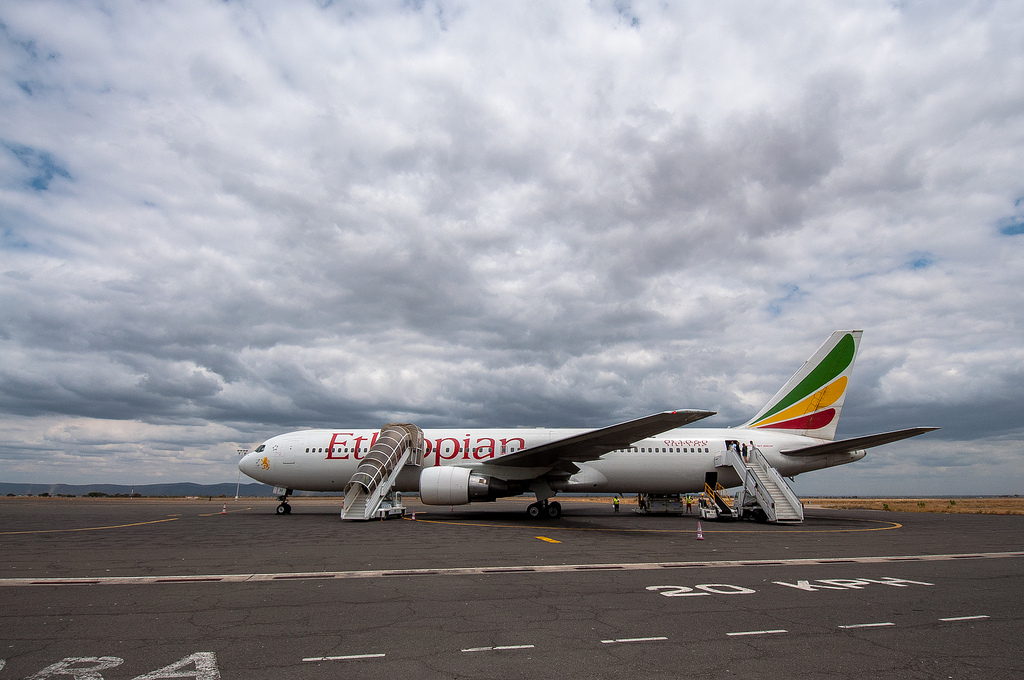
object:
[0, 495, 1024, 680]
runway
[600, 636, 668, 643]
line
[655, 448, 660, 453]
window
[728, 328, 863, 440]
tail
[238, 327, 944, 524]
aircraft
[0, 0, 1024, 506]
sky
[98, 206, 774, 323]
banks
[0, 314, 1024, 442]
cloud